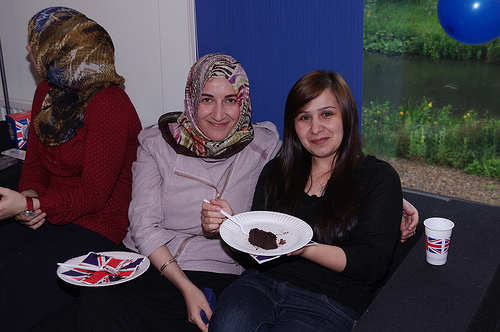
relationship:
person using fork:
[199, 71, 403, 330] [202, 194, 252, 231]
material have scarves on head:
[157, 51, 256, 161] [27, 3, 377, 158]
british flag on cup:
[424, 235, 441, 257] [424, 214, 454, 267]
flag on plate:
[60, 251, 146, 281] [52, 237, 156, 304]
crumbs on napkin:
[80, 253, 131, 287] [56, 246, 144, 286]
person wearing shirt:
[199, 71, 403, 330] [241, 149, 401, 309]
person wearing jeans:
[245, 57, 409, 330] [197, 260, 373, 330]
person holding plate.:
[199, 71, 403, 330] [208, 179, 324, 284]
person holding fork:
[199, 71, 403, 330] [195, 195, 253, 234]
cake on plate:
[247, 228, 277, 247] [218, 209, 315, 260]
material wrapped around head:
[157, 51, 253, 159] [183, 52, 253, 140]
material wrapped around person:
[25, 6, 124, 147] [0, 12, 139, 327]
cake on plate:
[238, 224, 313, 261] [208, 196, 345, 264]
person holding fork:
[199, 71, 403, 330] [198, 191, 249, 233]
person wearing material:
[135, 44, 275, 329] [157, 51, 256, 161]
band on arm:
[160, 258, 177, 271] [126, 142, 214, 330]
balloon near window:
[430, 5, 498, 62] [198, 7, 499, 206]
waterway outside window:
[364, 43, 499, 123] [359, 2, 499, 202]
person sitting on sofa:
[199, 71, 403, 330] [342, 181, 498, 330]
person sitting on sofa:
[135, 44, 275, 329] [342, 181, 498, 330]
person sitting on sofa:
[0, 12, 136, 332] [342, 181, 498, 330]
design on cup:
[425, 234, 454, 255] [424, 217, 454, 265]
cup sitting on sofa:
[424, 217, 454, 265] [403, 174, 498, 328]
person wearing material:
[199, 71, 403, 330] [157, 51, 256, 161]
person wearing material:
[0, 12, 136, 332] [25, 6, 124, 147]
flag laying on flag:
[60, 251, 146, 281] [76, 252, 126, 280]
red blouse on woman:
[16, 77, 141, 238] [0, 5, 142, 244]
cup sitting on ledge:
[419, 211, 459, 268] [368, 198, 498, 330]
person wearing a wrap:
[135, 44, 275, 329] [161, 49, 255, 153]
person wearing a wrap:
[0, 12, 136, 332] [20, 4, 117, 140]